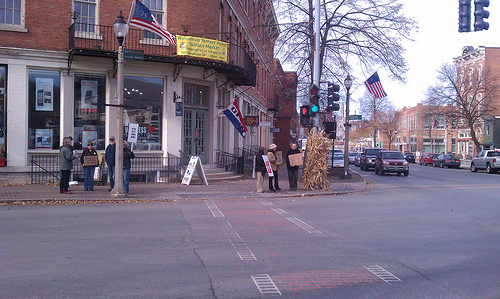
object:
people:
[58, 135, 81, 194]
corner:
[215, 130, 367, 205]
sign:
[180, 154, 211, 189]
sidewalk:
[6, 177, 281, 199]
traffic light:
[310, 86, 320, 113]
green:
[311, 106, 320, 113]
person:
[249, 149, 273, 195]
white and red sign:
[262, 156, 274, 176]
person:
[285, 139, 305, 192]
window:
[28, 67, 63, 149]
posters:
[35, 129, 53, 151]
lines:
[363, 264, 403, 285]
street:
[3, 174, 499, 298]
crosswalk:
[177, 194, 420, 298]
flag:
[131, 2, 173, 43]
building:
[1, 1, 280, 180]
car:
[472, 149, 499, 174]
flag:
[365, 72, 386, 100]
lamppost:
[342, 74, 352, 179]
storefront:
[1, 49, 264, 187]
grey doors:
[183, 107, 209, 166]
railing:
[33, 148, 183, 183]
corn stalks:
[300, 126, 329, 194]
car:
[374, 148, 407, 177]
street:
[344, 149, 500, 192]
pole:
[305, 0, 325, 189]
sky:
[271, 2, 499, 113]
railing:
[66, 23, 257, 92]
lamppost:
[105, 47, 130, 199]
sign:
[288, 153, 303, 167]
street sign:
[350, 115, 362, 122]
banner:
[175, 33, 231, 64]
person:
[124, 140, 135, 192]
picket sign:
[129, 120, 140, 147]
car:
[434, 149, 463, 170]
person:
[56, 131, 76, 192]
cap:
[270, 141, 278, 149]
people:
[255, 147, 268, 194]